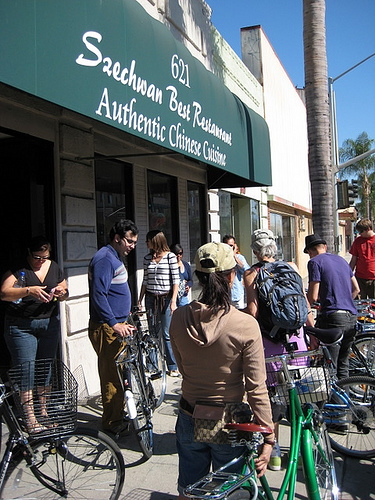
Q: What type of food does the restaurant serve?
A: Chinese.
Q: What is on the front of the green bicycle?
A: A basket.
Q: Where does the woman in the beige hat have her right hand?
A: On the bicycle.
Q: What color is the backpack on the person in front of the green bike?
A: Blue.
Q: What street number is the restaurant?
A: 621.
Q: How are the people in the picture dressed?
A: Casually.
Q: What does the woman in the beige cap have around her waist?
A: A purse.